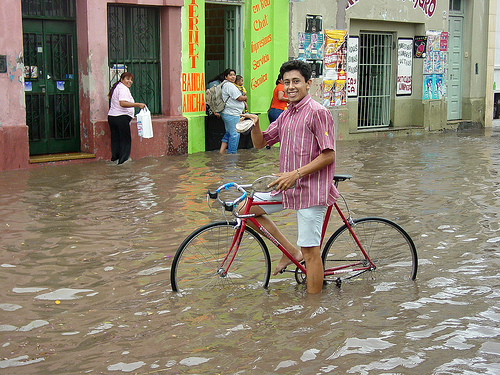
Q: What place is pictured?
A: It is a street.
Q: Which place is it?
A: It is a street.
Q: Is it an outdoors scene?
A: Yes, it is outdoors.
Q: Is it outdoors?
A: Yes, it is outdoors.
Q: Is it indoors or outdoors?
A: It is outdoors.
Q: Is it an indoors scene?
A: No, it is outdoors.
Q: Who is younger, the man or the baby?
A: The baby is younger than the man.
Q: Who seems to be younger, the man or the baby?
A: The baby is younger than the man.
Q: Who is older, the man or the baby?
A: The man is older than the baby.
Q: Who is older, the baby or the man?
A: The man is older than the baby.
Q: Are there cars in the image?
A: No, there are no cars.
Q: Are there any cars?
A: No, there are no cars.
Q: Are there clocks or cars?
A: No, there are no cars or clocks.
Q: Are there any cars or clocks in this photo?
A: No, there are no cars or clocks.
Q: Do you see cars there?
A: No, there are no cars.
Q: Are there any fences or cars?
A: No, there are no cars or fences.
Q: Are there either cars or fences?
A: No, there are no cars or fences.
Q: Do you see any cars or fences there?
A: No, there are no cars or fences.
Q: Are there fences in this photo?
A: No, there are no fences.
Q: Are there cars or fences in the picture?
A: No, there are no fences or cars.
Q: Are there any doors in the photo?
A: Yes, there is a door.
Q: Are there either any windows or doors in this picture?
A: Yes, there is a door.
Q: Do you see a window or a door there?
A: Yes, there is a door.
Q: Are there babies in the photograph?
A: Yes, there is a baby.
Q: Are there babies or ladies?
A: Yes, there is a baby.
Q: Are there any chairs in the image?
A: No, there are no chairs.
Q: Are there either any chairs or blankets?
A: No, there are no chairs or blankets.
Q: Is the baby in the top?
A: Yes, the baby is in the top of the image.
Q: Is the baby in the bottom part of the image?
A: No, the baby is in the top of the image.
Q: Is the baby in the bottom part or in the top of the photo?
A: The baby is in the top of the image.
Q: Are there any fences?
A: No, there are no fences.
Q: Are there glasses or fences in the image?
A: No, there are no fences or glasses.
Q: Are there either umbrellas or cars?
A: No, there are no cars or umbrellas.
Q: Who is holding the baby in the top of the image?
A: The people are holding the baby.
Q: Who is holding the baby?
A: The people are holding the baby.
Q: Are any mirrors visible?
A: No, there are no mirrors.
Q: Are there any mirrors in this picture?
A: No, there are no mirrors.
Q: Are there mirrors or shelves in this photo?
A: No, there are no mirrors or shelves.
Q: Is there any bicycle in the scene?
A: Yes, there is a bicycle.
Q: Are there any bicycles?
A: Yes, there is a bicycle.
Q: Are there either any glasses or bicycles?
A: Yes, there is a bicycle.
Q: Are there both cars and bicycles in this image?
A: No, there is a bicycle but no cars.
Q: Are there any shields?
A: No, there are no shields.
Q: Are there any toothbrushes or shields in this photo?
A: No, there are no shields or toothbrushes.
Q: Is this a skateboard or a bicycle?
A: This is a bicycle.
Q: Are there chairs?
A: No, there are no chairs.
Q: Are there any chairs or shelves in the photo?
A: No, there are no chairs or shelves.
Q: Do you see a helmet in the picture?
A: No, there are no helmets.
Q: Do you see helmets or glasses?
A: No, there are no helmets or glasses.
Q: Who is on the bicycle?
A: The man is on the bicycle.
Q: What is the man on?
A: The man is on the bicycle.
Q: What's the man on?
A: The man is on the bicycle.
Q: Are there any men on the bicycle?
A: Yes, there is a man on the bicycle.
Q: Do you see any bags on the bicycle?
A: No, there is a man on the bicycle.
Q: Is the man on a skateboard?
A: No, the man is on the bicycle.